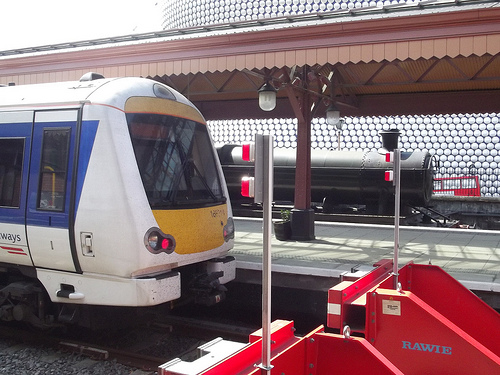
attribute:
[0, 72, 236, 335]
train — white, yellow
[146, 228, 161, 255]
light — headlight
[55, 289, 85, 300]
step — white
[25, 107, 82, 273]
door — blue, white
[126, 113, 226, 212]
windshield — large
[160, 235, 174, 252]
light — red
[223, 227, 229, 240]
light — red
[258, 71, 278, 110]
fixture — quaint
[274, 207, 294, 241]
plant — small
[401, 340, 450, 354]
word — written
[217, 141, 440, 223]
car — round, black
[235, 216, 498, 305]
platform — between tracks, concrete, covered, grey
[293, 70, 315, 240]
beam — tall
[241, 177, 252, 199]
light — red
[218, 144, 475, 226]
engine — old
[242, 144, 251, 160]
light — red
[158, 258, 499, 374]
stopper — red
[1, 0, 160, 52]
sky — white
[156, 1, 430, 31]
building — grey